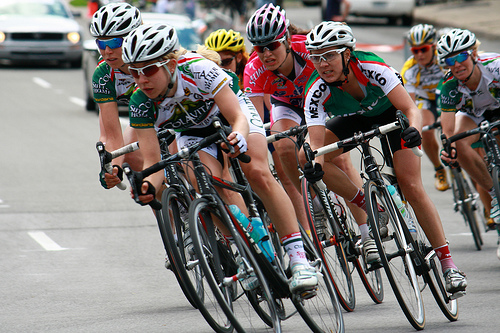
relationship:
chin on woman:
[320, 73, 346, 86] [103, 22, 315, 298]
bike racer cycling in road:
[120, 21, 317, 293] [2, 1, 499, 332]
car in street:
[0, 0, 83, 68] [6, 69, 86, 330]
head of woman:
[121, 19, 176, 104] [103, 22, 315, 298]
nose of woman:
[318, 60, 331, 71] [277, 13, 464, 230]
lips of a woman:
[138, 83, 158, 93] [103, 22, 315, 298]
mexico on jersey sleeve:
[307, 82, 323, 119] [301, 65, 338, 130]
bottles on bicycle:
[233, 199, 289, 274] [113, 99, 368, 322]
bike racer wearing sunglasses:
[120, 21, 317, 293] [126, 59, 168, 78]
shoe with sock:
[439, 265, 469, 293] [431, 242, 461, 276]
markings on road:
[28, 74, 91, 109] [2, 6, 496, 331]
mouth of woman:
[141, 85, 155, 96] [103, 22, 315, 298]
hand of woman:
[213, 131, 255, 163] [103, 22, 315, 298]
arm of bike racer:
[213, 81, 250, 155] [120, 21, 317, 293]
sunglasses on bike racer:
[130, 60, 170, 77] [120, 21, 317, 293]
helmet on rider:
[203, 26, 251, 60] [291, 15, 471, 305]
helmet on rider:
[203, 26, 251, 60] [113, 16, 328, 329]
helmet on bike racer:
[203, 26, 251, 60] [120, 21, 317, 293]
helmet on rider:
[203, 26, 251, 60] [230, 1, 389, 275]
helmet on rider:
[424, 23, 479, 68] [427, 24, 497, 260]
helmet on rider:
[203, 26, 251, 60] [391, 17, 463, 194]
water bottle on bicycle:
[221, 198, 280, 270] [132, 134, 344, 333]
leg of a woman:
[383, 136, 468, 267] [288, 26, 443, 265]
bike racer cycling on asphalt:
[120, 21, 317, 293] [2, 314, 482, 320]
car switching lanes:
[0, 5, 94, 74] [7, 58, 91, 106]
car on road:
[0, 0, 83, 68] [350, 21, 410, 44]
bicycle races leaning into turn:
[71, 2, 451, 300] [4, 223, 476, 325]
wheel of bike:
[365, 183, 435, 318] [317, 101, 417, 323]